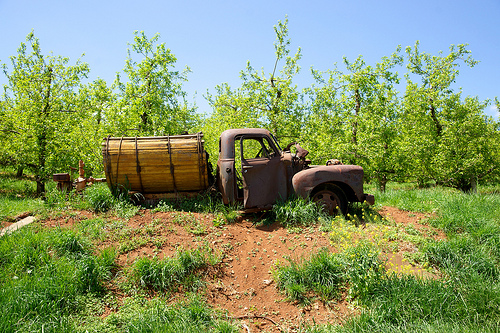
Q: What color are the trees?
A: Green.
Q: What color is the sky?
A: Blue.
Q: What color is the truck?
A: Brown.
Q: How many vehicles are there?
A: One.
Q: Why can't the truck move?
A: It's missing wheels.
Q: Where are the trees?
A: Behind the truck.